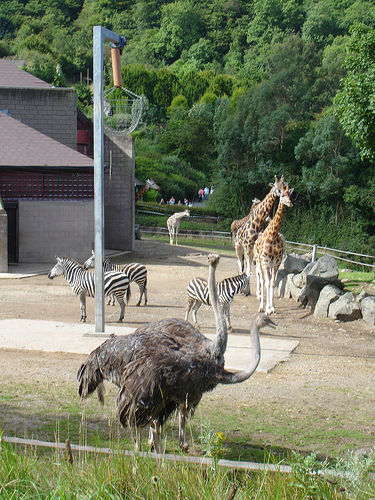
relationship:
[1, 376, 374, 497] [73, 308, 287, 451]
grass near emu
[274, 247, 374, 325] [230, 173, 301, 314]
stones near giraffes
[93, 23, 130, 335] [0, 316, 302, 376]
pole on pad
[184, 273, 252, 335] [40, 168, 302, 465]
zebra at romaing at zoo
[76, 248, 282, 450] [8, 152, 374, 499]
ostriches ar romaing at zoo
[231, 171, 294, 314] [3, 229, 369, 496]
giraffes are romaing at zoo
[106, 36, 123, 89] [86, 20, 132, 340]
basket attached to pole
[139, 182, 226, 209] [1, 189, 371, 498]
people walking on ground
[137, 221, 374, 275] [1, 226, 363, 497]
fence around enclosure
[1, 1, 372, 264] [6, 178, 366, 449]
trees are surrounding enclosure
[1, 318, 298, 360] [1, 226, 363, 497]
pad in enclosure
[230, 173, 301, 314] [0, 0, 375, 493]
giraffes are standing in zoo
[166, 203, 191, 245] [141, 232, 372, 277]
giraffe looking at grass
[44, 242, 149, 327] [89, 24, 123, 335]
zebras are standing by pole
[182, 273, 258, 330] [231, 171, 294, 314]
zebra next to giraffes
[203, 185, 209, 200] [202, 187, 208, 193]
people wears shirt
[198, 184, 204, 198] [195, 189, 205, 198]
woman wears shirt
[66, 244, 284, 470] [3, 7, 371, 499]
ostriches enjoys weather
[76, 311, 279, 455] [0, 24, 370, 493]
ostriches in zoo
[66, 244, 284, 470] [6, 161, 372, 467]
ostriches in zoo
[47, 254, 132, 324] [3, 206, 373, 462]
zebras in zoo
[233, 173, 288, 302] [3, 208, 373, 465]
giraffes in pen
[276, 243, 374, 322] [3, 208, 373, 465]
rocks in pen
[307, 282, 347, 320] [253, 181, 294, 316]
rocks next giraffes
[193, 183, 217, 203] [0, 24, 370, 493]
people in zoo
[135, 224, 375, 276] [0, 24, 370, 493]
fence in zoo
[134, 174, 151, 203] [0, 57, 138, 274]
giraffe behind building